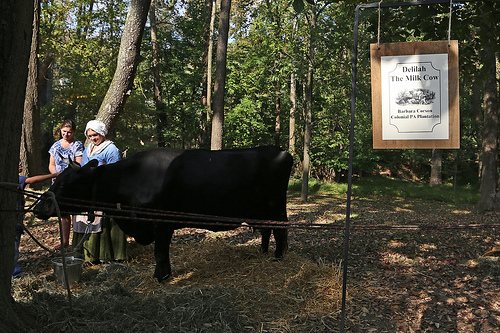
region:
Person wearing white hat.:
[81, 115, 123, 143]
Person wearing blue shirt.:
[84, 145, 131, 168]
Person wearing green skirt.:
[80, 226, 132, 267]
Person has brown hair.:
[54, 113, 95, 153]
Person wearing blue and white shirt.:
[29, 128, 102, 183]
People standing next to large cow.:
[38, 122, 122, 191]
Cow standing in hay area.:
[113, 217, 298, 278]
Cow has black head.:
[42, 160, 104, 226]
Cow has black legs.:
[146, 231, 183, 268]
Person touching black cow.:
[21, 163, 113, 189]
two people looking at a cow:
[28, 116, 302, 280]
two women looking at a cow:
[37, 114, 294, 279]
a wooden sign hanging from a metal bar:
[365, 0, 456, 150]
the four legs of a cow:
[145, 220, 295, 286]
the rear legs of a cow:
[250, 220, 285, 265]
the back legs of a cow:
[253, 220, 293, 262]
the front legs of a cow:
[140, 230, 175, 282]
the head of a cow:
[22, 155, 98, 221]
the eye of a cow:
[56, 180, 63, 190]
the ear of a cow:
[76, 156, 100, 171]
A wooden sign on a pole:
[364, 36, 473, 162]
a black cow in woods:
[32, 135, 299, 289]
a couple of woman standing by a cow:
[50, 122, 291, 275]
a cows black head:
[35, 153, 101, 225]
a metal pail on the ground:
[39, 251, 85, 295]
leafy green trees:
[163, 0, 355, 141]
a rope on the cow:
[26, 186, 67, 289]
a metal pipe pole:
[339, 8, 366, 319]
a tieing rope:
[118, 218, 492, 237]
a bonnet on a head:
[81, 123, 109, 144]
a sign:
[372, 53, 463, 153]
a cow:
[50, 145, 312, 270]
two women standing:
[51, 114, 110, 164]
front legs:
[152, 248, 182, 275]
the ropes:
[262, 210, 304, 239]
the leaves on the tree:
[231, 55, 282, 125]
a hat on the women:
[84, 118, 104, 133]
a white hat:
[86, 118, 106, 132]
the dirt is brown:
[379, 230, 450, 310]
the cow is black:
[69, 161, 313, 272]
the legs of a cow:
[140, 216, 290, 281]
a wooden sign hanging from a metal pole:
[360, 0, 465, 160]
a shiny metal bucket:
[46, 250, 81, 285]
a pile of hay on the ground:
[181, 255, 344, 331]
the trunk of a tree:
[476, 135, 498, 215]